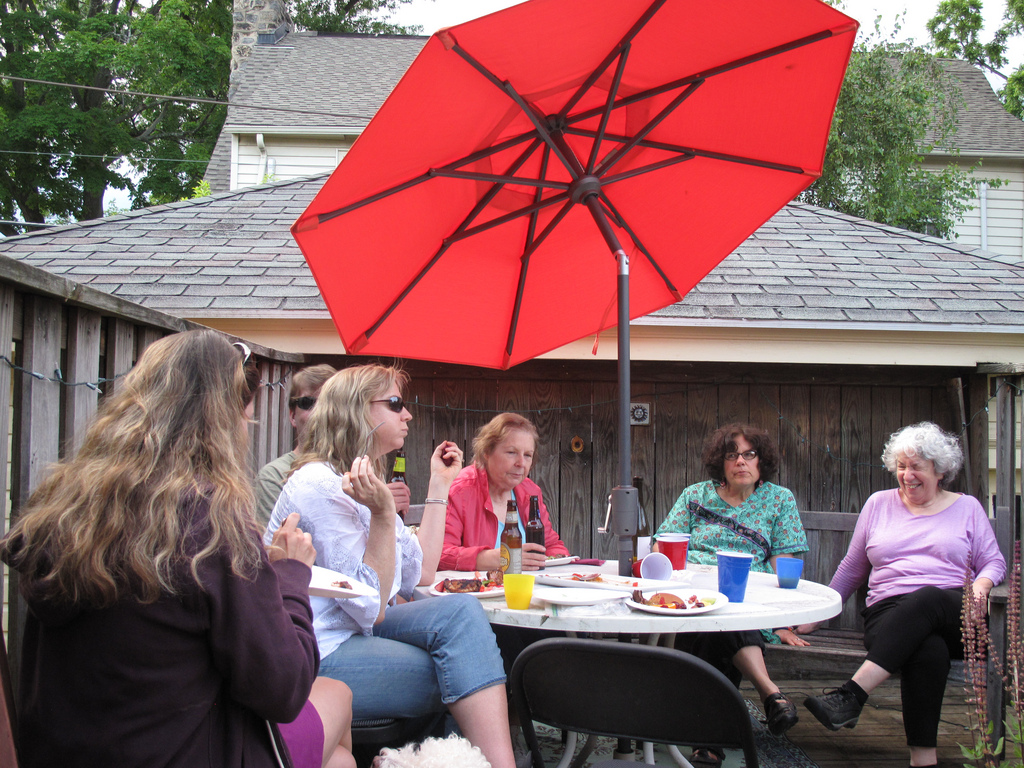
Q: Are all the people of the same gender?
A: Yes, all the people are female.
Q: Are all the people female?
A: Yes, all the people are female.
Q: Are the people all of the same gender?
A: Yes, all the people are female.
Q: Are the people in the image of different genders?
A: No, all the people are female.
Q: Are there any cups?
A: Yes, there is a cup.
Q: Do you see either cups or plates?
A: Yes, there is a cup.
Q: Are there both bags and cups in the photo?
A: No, there is a cup but no bags.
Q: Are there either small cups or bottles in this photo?
A: Yes, there is a small cup.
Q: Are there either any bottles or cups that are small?
A: Yes, the cup is small.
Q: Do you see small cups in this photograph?
A: Yes, there is a small cup.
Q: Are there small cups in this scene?
A: Yes, there is a small cup.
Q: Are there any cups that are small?
A: Yes, there is a cup that is small.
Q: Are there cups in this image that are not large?
A: Yes, there is a small cup.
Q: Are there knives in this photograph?
A: No, there are no knives.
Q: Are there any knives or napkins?
A: No, there are no knives or napkins.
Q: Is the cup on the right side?
A: Yes, the cup is on the right of the image.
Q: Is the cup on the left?
A: No, the cup is on the right of the image.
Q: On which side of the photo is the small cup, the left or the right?
A: The cup is on the right of the image.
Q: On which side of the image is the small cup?
A: The cup is on the right of the image.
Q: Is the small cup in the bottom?
A: Yes, the cup is in the bottom of the image.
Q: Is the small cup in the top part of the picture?
A: No, the cup is in the bottom of the image.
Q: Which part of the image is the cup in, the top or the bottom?
A: The cup is in the bottom of the image.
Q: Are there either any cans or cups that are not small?
A: No, there is a cup but it is small.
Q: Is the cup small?
A: Yes, the cup is small.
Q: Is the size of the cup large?
A: No, the cup is small.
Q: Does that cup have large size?
A: No, the cup is small.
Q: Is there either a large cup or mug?
A: No, there is a cup but it is small.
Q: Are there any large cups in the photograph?
A: No, there is a cup but it is small.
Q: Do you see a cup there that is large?
A: No, there is a cup but it is small.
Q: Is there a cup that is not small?
A: No, there is a cup but it is small.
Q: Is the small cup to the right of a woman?
A: Yes, the cup is to the right of a woman.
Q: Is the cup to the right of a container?
A: No, the cup is to the right of a woman.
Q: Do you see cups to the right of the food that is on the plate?
A: Yes, there is a cup to the right of the food.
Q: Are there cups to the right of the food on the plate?
A: Yes, there is a cup to the right of the food.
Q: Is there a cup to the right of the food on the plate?
A: Yes, there is a cup to the right of the food.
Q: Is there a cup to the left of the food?
A: No, the cup is to the right of the food.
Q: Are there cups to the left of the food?
A: No, the cup is to the right of the food.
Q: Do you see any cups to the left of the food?
A: No, the cup is to the right of the food.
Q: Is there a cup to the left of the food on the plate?
A: No, the cup is to the right of the food.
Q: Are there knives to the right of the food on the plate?
A: No, there is a cup to the right of the food.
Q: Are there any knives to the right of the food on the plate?
A: No, there is a cup to the right of the food.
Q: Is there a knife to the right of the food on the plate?
A: No, there is a cup to the right of the food.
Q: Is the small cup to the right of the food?
A: Yes, the cup is to the right of the food.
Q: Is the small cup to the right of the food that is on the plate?
A: Yes, the cup is to the right of the food.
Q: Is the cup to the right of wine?
A: No, the cup is to the right of the food.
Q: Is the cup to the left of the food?
A: No, the cup is to the right of the food.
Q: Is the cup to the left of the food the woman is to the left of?
A: No, the cup is to the right of the food.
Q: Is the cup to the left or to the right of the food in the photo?
A: The cup is to the right of the food.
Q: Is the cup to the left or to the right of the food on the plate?
A: The cup is to the right of the food.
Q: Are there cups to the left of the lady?
A: Yes, there is a cup to the left of the lady.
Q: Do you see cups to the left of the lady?
A: Yes, there is a cup to the left of the lady.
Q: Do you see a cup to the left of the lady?
A: Yes, there is a cup to the left of the lady.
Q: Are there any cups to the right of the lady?
A: No, the cup is to the left of the lady.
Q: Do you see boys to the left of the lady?
A: No, there is a cup to the left of the lady.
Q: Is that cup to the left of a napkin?
A: No, the cup is to the left of the lady.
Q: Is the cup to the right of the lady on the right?
A: No, the cup is to the left of the lady.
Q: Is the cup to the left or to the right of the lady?
A: The cup is to the left of the lady.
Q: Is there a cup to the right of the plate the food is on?
A: Yes, there is a cup to the right of the plate.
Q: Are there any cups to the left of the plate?
A: No, the cup is to the right of the plate.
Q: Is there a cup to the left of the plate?
A: No, the cup is to the right of the plate.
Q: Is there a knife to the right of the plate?
A: No, there is a cup to the right of the plate.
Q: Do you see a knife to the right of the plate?
A: No, there is a cup to the right of the plate.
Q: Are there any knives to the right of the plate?
A: No, there is a cup to the right of the plate.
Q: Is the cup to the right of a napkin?
A: No, the cup is to the right of the plate.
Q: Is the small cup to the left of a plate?
A: No, the cup is to the right of a plate.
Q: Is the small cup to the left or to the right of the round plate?
A: The cup is to the right of the plate.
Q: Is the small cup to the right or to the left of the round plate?
A: The cup is to the right of the plate.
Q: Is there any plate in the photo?
A: Yes, there is a plate.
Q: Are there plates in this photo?
A: Yes, there is a plate.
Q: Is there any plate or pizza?
A: Yes, there is a plate.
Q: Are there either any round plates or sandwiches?
A: Yes, there is a round plate.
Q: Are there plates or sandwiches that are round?
A: Yes, the plate is round.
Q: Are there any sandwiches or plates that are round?
A: Yes, the plate is round.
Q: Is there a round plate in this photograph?
A: Yes, there is a round plate.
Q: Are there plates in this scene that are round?
A: Yes, there is a plate that is round.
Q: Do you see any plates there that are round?
A: Yes, there is a plate that is round.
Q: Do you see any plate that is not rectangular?
A: Yes, there is a round plate.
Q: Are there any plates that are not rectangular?
A: Yes, there is a round plate.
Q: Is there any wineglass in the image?
A: No, there are no wine glasses.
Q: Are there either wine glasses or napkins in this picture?
A: No, there are no wine glasses or napkins.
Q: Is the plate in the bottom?
A: Yes, the plate is in the bottom of the image.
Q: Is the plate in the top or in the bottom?
A: The plate is in the bottom of the image.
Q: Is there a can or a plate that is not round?
A: No, there is a plate but it is round.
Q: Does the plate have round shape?
A: Yes, the plate is round.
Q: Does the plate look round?
A: Yes, the plate is round.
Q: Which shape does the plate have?
A: The plate has round shape.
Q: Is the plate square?
A: No, the plate is round.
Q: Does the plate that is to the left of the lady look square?
A: No, the plate is round.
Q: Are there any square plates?
A: No, there is a plate but it is round.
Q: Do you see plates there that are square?
A: No, there is a plate but it is round.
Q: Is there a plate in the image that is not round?
A: No, there is a plate but it is round.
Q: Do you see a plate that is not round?
A: No, there is a plate but it is round.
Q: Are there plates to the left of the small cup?
A: Yes, there is a plate to the left of the cup.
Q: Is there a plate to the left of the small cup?
A: Yes, there is a plate to the left of the cup.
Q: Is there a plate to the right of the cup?
A: No, the plate is to the left of the cup.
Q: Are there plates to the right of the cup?
A: No, the plate is to the left of the cup.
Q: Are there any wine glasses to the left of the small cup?
A: No, there is a plate to the left of the cup.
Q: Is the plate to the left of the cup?
A: Yes, the plate is to the left of the cup.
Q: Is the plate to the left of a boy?
A: No, the plate is to the left of the cup.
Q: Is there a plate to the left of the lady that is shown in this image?
A: Yes, there is a plate to the left of the lady.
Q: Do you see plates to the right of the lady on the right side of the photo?
A: No, the plate is to the left of the lady.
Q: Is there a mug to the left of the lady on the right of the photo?
A: No, there is a plate to the left of the lady.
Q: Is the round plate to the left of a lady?
A: Yes, the plate is to the left of a lady.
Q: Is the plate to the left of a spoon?
A: No, the plate is to the left of a lady.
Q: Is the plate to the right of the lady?
A: No, the plate is to the left of the lady.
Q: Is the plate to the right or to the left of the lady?
A: The plate is to the left of the lady.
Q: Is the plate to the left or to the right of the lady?
A: The plate is to the left of the lady.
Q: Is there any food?
A: Yes, there is food.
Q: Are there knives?
A: No, there are no knives.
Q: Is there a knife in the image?
A: No, there are no knives.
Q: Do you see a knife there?
A: No, there are no knives.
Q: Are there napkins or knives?
A: No, there are no knives or napkins.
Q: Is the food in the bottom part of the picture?
A: Yes, the food is in the bottom of the image.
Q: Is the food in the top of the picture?
A: No, the food is in the bottom of the image.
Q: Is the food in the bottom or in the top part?
A: The food is in the bottom of the image.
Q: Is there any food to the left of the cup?
A: Yes, there is food to the left of the cup.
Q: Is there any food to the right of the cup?
A: No, the food is to the left of the cup.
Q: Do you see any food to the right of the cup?
A: No, the food is to the left of the cup.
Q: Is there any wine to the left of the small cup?
A: No, there is food to the left of the cup.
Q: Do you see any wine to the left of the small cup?
A: No, there is food to the left of the cup.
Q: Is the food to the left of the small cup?
A: Yes, the food is to the left of the cup.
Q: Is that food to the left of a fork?
A: No, the food is to the left of the cup.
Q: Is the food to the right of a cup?
A: No, the food is to the left of a cup.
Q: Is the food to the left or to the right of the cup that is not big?
A: The food is to the left of the cup.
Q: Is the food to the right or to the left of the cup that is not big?
A: The food is to the left of the cup.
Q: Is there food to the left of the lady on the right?
A: Yes, there is food to the left of the lady.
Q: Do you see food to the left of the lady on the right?
A: Yes, there is food to the left of the lady.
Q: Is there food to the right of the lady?
A: No, the food is to the left of the lady.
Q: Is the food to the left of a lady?
A: Yes, the food is to the left of a lady.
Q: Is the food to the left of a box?
A: No, the food is to the left of a lady.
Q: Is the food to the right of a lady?
A: No, the food is to the left of a lady.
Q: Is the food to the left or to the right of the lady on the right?
A: The food is to the left of the lady.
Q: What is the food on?
A: The food is on the plate.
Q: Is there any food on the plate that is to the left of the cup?
A: Yes, there is food on the plate.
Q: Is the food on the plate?
A: Yes, the food is on the plate.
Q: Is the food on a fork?
A: No, the food is on the plate.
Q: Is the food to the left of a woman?
A: No, the food is to the right of a woman.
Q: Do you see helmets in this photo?
A: No, there are no helmets.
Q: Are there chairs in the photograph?
A: Yes, there is a chair.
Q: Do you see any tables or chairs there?
A: Yes, there is a chair.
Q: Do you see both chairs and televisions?
A: No, there is a chair but no televisions.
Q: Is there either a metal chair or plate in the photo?
A: Yes, there is a metal chair.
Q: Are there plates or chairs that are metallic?
A: Yes, the chair is metallic.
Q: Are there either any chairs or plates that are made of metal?
A: Yes, the chair is made of metal.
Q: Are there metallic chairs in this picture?
A: Yes, there is a metal chair.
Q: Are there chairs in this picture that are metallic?
A: Yes, there is a chair that is metallic.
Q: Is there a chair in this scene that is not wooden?
A: Yes, there is a metallic chair.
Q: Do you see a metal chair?
A: Yes, there is a chair that is made of metal.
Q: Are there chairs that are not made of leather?
A: Yes, there is a chair that is made of metal.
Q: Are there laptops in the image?
A: No, there are no laptops.